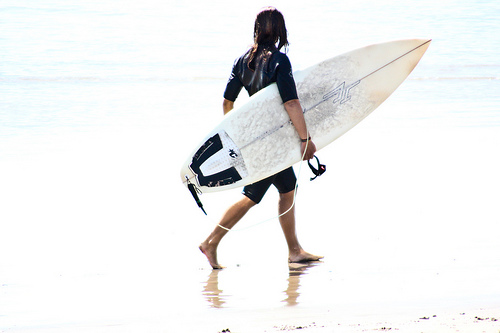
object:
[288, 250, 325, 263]
left foot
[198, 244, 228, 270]
right foot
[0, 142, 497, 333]
beach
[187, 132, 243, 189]
zline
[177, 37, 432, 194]
surfboard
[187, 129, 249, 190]
bottom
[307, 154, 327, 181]
sunglasses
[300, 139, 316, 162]
hand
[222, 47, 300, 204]
wetsuit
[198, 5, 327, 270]
guy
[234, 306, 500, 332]
sand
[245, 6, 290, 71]
hair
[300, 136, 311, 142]
wristband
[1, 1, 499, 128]
water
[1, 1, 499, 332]
photo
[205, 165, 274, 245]
legs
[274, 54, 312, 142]
arm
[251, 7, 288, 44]
head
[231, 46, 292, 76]
shoulders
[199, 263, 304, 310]
shadows